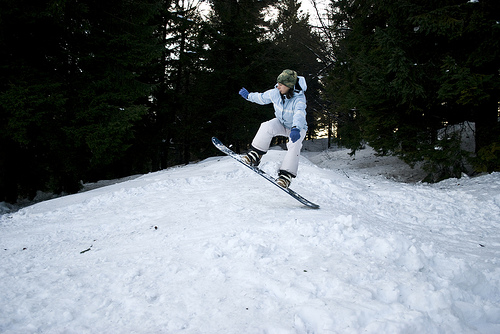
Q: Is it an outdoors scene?
A: Yes, it is outdoors.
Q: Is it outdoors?
A: Yes, it is outdoors.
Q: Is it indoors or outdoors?
A: It is outdoors.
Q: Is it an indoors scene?
A: No, it is outdoors.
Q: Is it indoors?
A: No, it is outdoors.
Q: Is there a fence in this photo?
A: No, there are no fences.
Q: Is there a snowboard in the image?
A: Yes, there is a snowboard.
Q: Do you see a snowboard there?
A: Yes, there is a snowboard.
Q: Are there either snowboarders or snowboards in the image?
A: Yes, there is a snowboard.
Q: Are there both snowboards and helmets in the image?
A: No, there is a snowboard but no helmets.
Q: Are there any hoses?
A: No, there are no hoses.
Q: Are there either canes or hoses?
A: No, there are no hoses or canes.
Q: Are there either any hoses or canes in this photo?
A: No, there are no hoses or canes.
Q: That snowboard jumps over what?
A: The snowboard jumps over the hill.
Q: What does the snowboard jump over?
A: The snowboard jumps over the hill.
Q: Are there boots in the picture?
A: Yes, there are boots.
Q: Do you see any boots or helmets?
A: Yes, there are boots.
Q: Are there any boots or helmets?
A: Yes, there are boots.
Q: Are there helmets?
A: No, there are no helmets.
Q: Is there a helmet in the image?
A: No, there are no helmets.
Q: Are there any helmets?
A: No, there are no helmets.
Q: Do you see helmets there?
A: No, there are no helmets.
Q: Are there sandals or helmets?
A: No, there are no helmets or sandals.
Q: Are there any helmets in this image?
A: No, there are no helmets.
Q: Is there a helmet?
A: No, there are no helmets.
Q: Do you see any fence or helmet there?
A: No, there are no helmets or fences.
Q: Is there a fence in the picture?
A: No, there are no fences.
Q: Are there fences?
A: No, there are no fences.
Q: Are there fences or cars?
A: No, there are no fences or cars.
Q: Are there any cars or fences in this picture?
A: No, there are no fences or cars.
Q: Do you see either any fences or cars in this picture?
A: No, there are no fences or cars.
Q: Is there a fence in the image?
A: No, there are no fences.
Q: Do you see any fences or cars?
A: No, there are no fences or cars.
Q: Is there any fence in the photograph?
A: No, there are no fences.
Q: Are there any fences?
A: No, there are no fences.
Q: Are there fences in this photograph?
A: No, there are no fences.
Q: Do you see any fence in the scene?
A: No, there are no fences.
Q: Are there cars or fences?
A: No, there are no fences or cars.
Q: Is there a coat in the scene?
A: Yes, there is a coat.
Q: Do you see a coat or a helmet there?
A: Yes, there is a coat.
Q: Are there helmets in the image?
A: No, there are no helmets.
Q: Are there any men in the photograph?
A: No, there are no men.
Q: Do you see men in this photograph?
A: No, there are no men.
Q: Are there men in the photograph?
A: No, there are no men.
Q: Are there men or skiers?
A: No, there are no men or skiers.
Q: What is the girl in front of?
A: The girl is in front of the tree.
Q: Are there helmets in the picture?
A: No, there are no helmets.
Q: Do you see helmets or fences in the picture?
A: No, there are no helmets or fences.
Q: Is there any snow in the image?
A: Yes, there is snow.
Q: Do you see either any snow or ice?
A: Yes, there is snow.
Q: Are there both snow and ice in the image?
A: No, there is snow but no ice.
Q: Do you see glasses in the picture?
A: No, there are no glasses.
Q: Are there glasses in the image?
A: No, there are no glasses.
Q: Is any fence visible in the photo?
A: No, there are no fences.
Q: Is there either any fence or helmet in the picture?
A: No, there are no fences or helmets.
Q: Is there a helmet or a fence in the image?
A: No, there are no fences or helmets.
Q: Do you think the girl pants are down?
A: Yes, the trousers are down.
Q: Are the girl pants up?
A: No, the pants are down.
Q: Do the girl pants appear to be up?
A: No, the trousers are down.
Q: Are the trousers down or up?
A: The trousers are down.